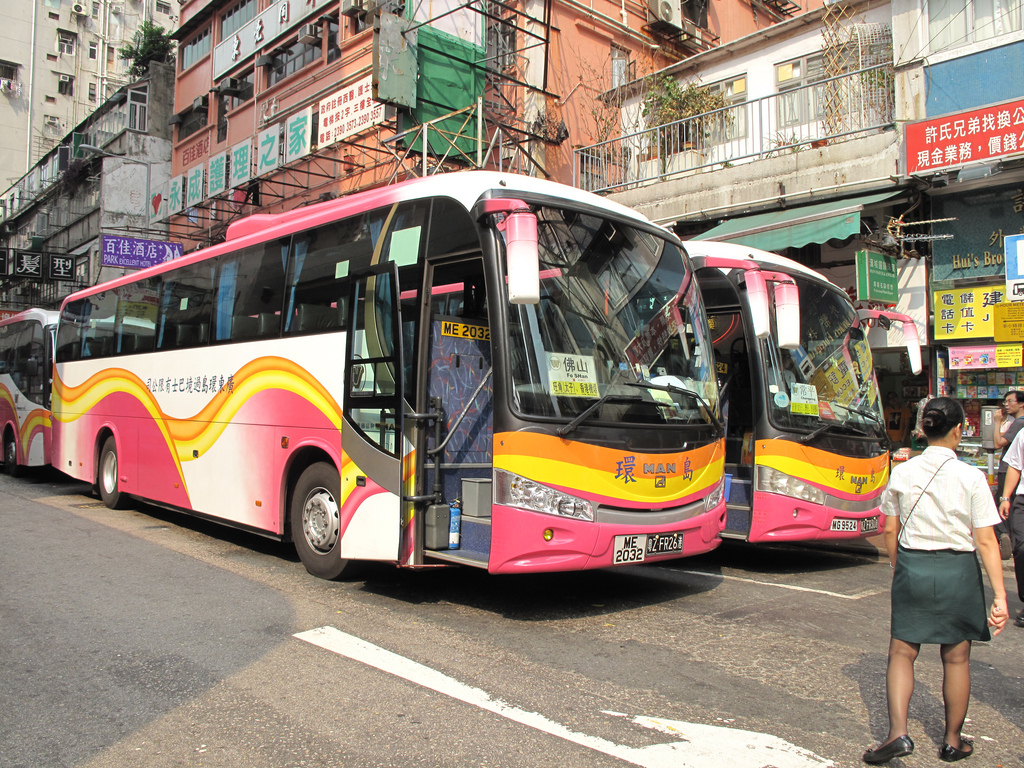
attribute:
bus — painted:
[45, 165, 728, 582]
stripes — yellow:
[41, 366, 355, 462]